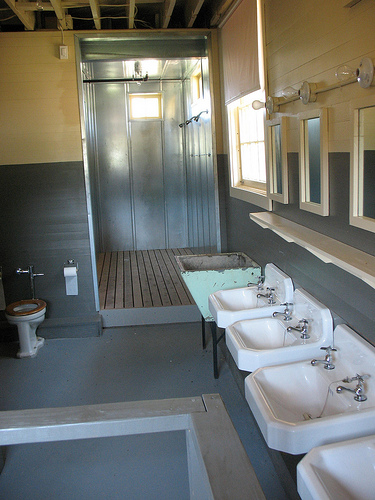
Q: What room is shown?
A: It is a bathroom.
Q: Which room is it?
A: It is a bathroom.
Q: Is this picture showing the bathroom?
A: Yes, it is showing the bathroom.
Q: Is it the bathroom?
A: Yes, it is the bathroom.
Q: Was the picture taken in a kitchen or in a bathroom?
A: It was taken at a bathroom.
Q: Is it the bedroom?
A: No, it is the bathroom.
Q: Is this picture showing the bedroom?
A: No, the picture is showing the bathroom.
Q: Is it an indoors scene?
A: Yes, it is indoors.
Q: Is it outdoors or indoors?
A: It is indoors.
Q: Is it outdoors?
A: No, it is indoors.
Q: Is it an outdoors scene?
A: No, it is indoors.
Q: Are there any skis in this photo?
A: No, there are no skis.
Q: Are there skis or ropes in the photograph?
A: No, there are no skis or ropes.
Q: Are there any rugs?
A: No, there are no rugs.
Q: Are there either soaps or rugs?
A: No, there are no rugs or soaps.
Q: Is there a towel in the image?
A: No, there are no towels.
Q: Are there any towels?
A: No, there are no towels.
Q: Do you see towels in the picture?
A: No, there are no towels.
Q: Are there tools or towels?
A: No, there are no towels or tools.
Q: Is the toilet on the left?
A: Yes, the toilet is on the left of the image.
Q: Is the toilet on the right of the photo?
A: No, the toilet is on the left of the image.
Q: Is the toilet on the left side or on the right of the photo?
A: The toilet is on the left of the image.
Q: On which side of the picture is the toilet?
A: The toilet is on the left of the image.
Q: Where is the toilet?
A: The toilet is in the bathroom.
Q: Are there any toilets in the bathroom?
A: Yes, there is a toilet in the bathroom.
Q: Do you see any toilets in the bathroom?
A: Yes, there is a toilet in the bathroom.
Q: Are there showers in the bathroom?
A: No, there is a toilet in the bathroom.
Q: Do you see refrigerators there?
A: No, there are no refrigerators.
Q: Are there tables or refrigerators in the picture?
A: No, there are no refrigerators or tables.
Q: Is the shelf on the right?
A: Yes, the shelf is on the right of the image.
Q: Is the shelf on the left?
A: No, the shelf is on the right of the image.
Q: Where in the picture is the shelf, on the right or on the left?
A: The shelf is on the right of the image.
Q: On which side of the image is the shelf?
A: The shelf is on the right of the image.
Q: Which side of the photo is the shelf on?
A: The shelf is on the right of the image.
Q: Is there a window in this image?
A: Yes, there is a window.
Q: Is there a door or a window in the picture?
A: Yes, there is a window.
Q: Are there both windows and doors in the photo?
A: No, there is a window but no doors.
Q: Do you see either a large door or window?
A: Yes, there is a large window.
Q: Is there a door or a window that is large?
A: Yes, the window is large.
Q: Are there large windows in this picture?
A: Yes, there is a large window.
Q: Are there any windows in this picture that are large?
A: Yes, there is a window that is large.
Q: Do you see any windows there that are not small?
A: Yes, there is a large window.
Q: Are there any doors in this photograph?
A: No, there are no doors.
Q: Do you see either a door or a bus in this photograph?
A: No, there are no doors or buses.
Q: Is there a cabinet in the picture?
A: No, there are no cabinets.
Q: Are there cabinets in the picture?
A: No, there are no cabinets.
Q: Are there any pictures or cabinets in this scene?
A: No, there are no cabinets or pictures.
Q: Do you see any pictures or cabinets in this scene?
A: No, there are no cabinets or pictures.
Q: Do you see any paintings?
A: No, there are no paintings.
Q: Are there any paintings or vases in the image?
A: No, there are no paintings or vases.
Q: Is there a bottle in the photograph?
A: No, there are no bottles.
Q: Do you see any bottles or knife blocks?
A: No, there are no bottles or knife blocks.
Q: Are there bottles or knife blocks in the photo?
A: No, there are no bottles or knife blocks.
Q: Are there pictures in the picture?
A: No, there are no pictures.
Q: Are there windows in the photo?
A: Yes, there is a window.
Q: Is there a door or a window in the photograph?
A: Yes, there is a window.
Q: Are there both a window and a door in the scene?
A: No, there is a window but no doors.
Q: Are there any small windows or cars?
A: Yes, there is a small window.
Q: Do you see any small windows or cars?
A: Yes, there is a small window.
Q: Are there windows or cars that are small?
A: Yes, the window is small.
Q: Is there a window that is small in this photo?
A: Yes, there is a small window.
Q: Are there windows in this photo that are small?
A: Yes, there is a window that is small.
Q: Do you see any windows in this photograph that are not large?
A: Yes, there is a small window.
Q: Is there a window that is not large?
A: Yes, there is a small window.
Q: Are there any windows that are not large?
A: Yes, there is a small window.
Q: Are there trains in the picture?
A: No, there are no trains.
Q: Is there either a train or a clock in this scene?
A: No, there are no trains or clocks.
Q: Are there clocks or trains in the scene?
A: No, there are no trains or clocks.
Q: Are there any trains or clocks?
A: No, there are no trains or clocks.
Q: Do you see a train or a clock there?
A: No, there are no trains or clocks.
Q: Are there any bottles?
A: No, there are no bottles.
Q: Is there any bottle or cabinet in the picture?
A: No, there are no bottles or cabinets.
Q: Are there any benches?
A: No, there are no benches.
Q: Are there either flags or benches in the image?
A: No, there are no benches or flags.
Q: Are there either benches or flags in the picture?
A: No, there are no benches or flags.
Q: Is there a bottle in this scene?
A: No, there are no bottles.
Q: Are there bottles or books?
A: No, there are no bottles or books.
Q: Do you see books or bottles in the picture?
A: No, there are no bottles or books.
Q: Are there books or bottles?
A: No, there are no bottles or books.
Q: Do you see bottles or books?
A: No, there are no bottles or books.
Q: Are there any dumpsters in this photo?
A: No, there are no dumpsters.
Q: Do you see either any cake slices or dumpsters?
A: No, there are no dumpsters or cake slices.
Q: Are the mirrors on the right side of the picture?
A: Yes, the mirrors are on the right of the image.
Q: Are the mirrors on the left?
A: No, the mirrors are on the right of the image.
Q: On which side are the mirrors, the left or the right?
A: The mirrors are on the right of the image.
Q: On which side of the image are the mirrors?
A: The mirrors are on the right of the image.